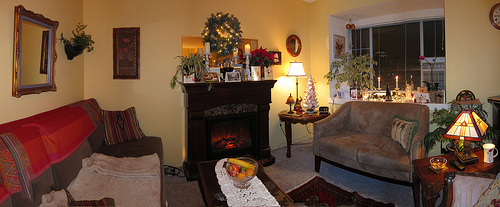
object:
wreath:
[201, 13, 243, 52]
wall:
[449, 0, 499, 84]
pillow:
[97, 103, 148, 147]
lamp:
[443, 107, 489, 165]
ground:
[448, 59, 468, 88]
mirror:
[11, 5, 58, 99]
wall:
[10, 82, 74, 113]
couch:
[313, 101, 429, 205]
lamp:
[286, 60, 308, 111]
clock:
[488, 3, 499, 30]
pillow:
[390, 115, 419, 153]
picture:
[113, 27, 142, 80]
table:
[195, 154, 295, 206]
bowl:
[226, 157, 259, 189]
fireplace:
[188, 71, 293, 178]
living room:
[1, 3, 499, 207]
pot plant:
[169, 53, 216, 91]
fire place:
[209, 120, 252, 153]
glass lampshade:
[443, 107, 489, 141]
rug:
[288, 175, 395, 206]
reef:
[209, 36, 219, 45]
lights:
[228, 32, 240, 45]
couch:
[0, 98, 164, 207]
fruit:
[226, 158, 256, 181]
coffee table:
[194, 155, 298, 207]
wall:
[83, 2, 311, 150]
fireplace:
[178, 73, 278, 175]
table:
[278, 107, 331, 158]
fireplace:
[181, 80, 276, 176]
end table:
[410, 146, 499, 206]